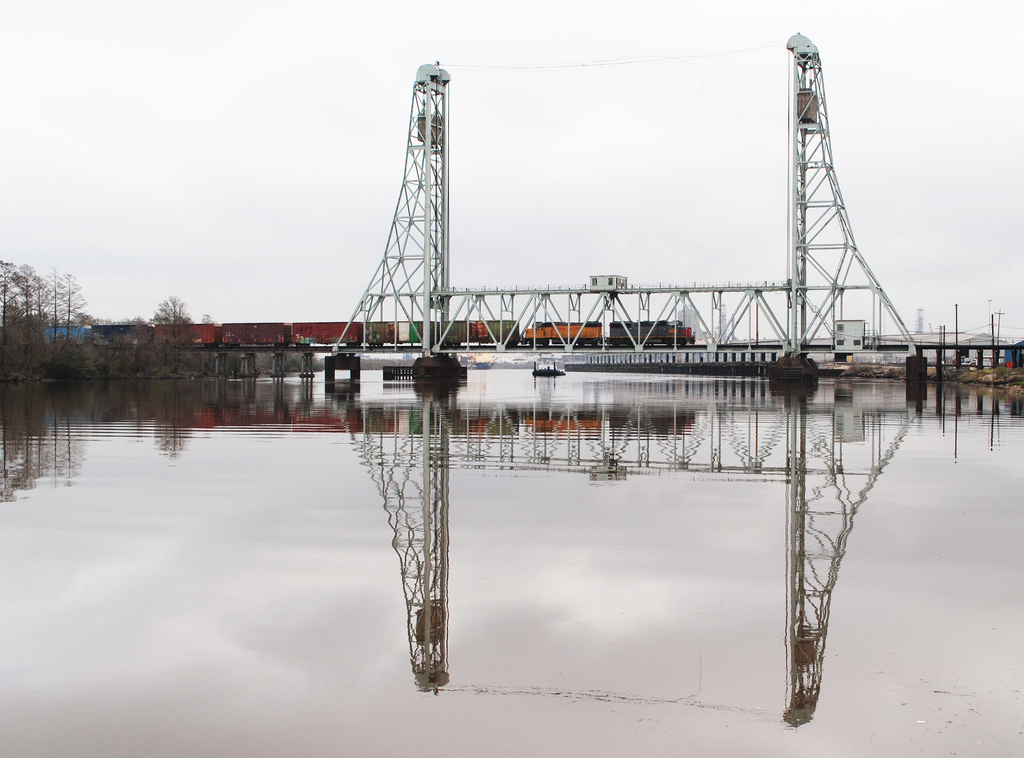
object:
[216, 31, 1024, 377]
bridge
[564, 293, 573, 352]
pole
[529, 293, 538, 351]
pole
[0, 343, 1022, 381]
tracks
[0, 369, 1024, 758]
lake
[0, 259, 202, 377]
trees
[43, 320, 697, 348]
train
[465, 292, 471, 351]
pole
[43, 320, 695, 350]
locomotive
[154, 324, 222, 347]
cargo trailer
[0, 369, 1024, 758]
water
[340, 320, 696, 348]
train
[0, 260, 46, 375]
leaves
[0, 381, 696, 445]
ripples